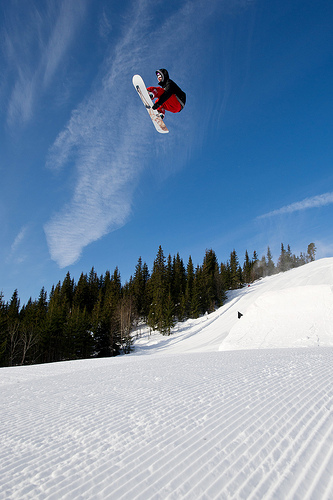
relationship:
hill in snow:
[34, 255, 330, 354] [248, 382, 318, 433]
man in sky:
[146, 67, 185, 119] [1, 2, 330, 287]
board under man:
[131, 76, 168, 134] [146, 67, 185, 119]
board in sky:
[131, 76, 168, 134] [1, 2, 330, 287]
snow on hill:
[248, 382, 318, 433] [34, 255, 330, 354]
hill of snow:
[34, 255, 330, 354] [248, 382, 318, 433]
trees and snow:
[1, 238, 314, 365] [248, 382, 318, 433]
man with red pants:
[146, 67, 185, 119] [148, 88, 182, 120]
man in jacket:
[146, 67, 185, 119] [154, 65, 186, 112]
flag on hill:
[237, 311, 247, 322] [34, 255, 330, 354]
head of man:
[154, 68, 172, 82] [146, 67, 185, 119]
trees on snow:
[1, 238, 314, 365] [248, 382, 318, 433]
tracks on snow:
[7, 387, 154, 499] [248, 382, 318, 433]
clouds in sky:
[1, 2, 200, 253] [1, 2, 330, 287]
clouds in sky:
[0, 0, 333, 312] [1, 2, 330, 287]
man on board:
[146, 67, 185, 119] [131, 76, 168, 134]